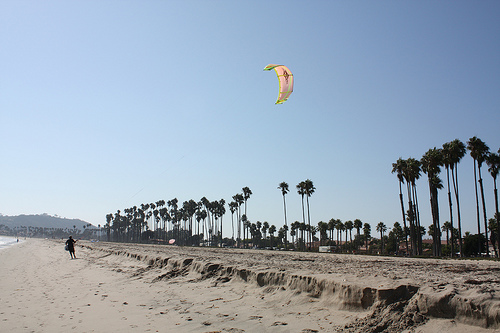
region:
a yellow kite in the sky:
[202, 53, 299, 107]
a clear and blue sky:
[95, 38, 172, 96]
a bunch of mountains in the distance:
[22, 202, 62, 234]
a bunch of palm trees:
[110, 202, 147, 222]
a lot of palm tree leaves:
[165, 193, 196, 214]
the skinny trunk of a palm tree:
[152, 226, 190, 241]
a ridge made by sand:
[212, 253, 267, 298]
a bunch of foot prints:
[95, 275, 155, 316]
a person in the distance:
[52, 228, 87, 259]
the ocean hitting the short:
[7, 235, 19, 263]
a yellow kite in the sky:
[238, 46, 322, 128]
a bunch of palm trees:
[115, 192, 189, 239]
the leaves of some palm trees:
[171, 195, 206, 216]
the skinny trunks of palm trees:
[200, 215, 231, 235]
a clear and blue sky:
[327, 116, 399, 173]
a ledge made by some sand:
[331, 272, 373, 307]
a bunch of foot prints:
[128, 288, 198, 323]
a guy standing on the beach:
[60, 229, 87, 261]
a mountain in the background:
[34, 203, 75, 234]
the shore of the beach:
[4, 232, 28, 246]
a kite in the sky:
[255, 56, 303, 108]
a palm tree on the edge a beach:
[275, 177, 292, 252]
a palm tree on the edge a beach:
[241, 183, 251, 246]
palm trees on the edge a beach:
[293, 180, 317, 247]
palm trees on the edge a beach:
[390, 155, 424, 248]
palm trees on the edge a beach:
[464, 133, 491, 255]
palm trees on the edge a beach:
[437, 138, 467, 252]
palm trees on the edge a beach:
[225, 181, 255, 246]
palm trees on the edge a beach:
[178, 196, 198, 241]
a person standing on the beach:
[57, 233, 91, 262]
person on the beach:
[66, 223, 87, 261]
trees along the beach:
[96, 138, 498, 248]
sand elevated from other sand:
[157, 245, 421, 288]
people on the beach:
[10, 232, 32, 252]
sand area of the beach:
[20, 243, 467, 323]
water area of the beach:
[2, 231, 17, 246]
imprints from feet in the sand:
[86, 280, 219, 330]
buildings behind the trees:
[290, 207, 470, 252]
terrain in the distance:
[5, 207, 93, 225]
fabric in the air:
[259, 53, 305, 114]